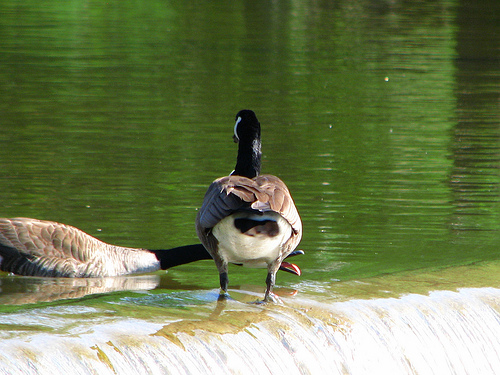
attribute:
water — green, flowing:
[129, 27, 389, 79]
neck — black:
[237, 143, 276, 170]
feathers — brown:
[222, 181, 299, 216]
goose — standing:
[197, 233, 300, 311]